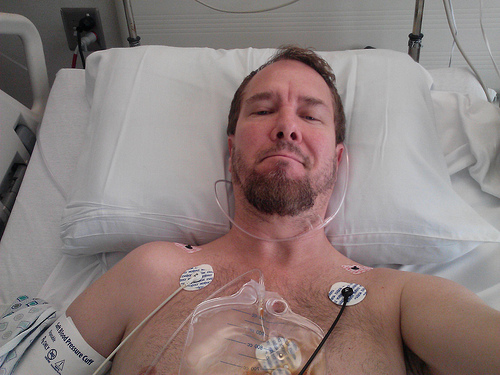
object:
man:
[8, 45, 499, 375]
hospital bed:
[0, 66, 500, 375]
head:
[228, 57, 346, 213]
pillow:
[58, 45, 500, 265]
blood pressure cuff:
[14, 317, 112, 375]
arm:
[17, 239, 183, 374]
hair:
[226, 43, 346, 145]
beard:
[228, 141, 339, 217]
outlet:
[58, 7, 107, 50]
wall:
[0, 0, 500, 109]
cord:
[72, 45, 79, 68]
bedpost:
[407, 0, 424, 63]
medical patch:
[327, 280, 365, 306]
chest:
[110, 265, 410, 374]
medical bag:
[176, 280, 327, 375]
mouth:
[256, 150, 307, 169]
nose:
[269, 105, 303, 143]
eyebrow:
[245, 91, 276, 104]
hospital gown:
[0, 294, 58, 375]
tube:
[143, 268, 265, 374]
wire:
[295, 289, 352, 375]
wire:
[92, 276, 200, 374]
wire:
[213, 143, 349, 243]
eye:
[300, 110, 325, 126]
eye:
[249, 106, 274, 118]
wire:
[174, 242, 202, 253]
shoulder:
[102, 241, 205, 307]